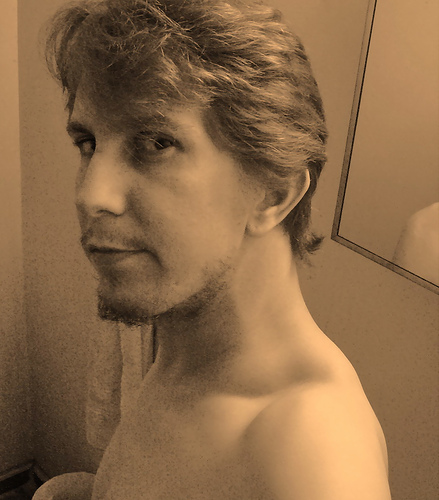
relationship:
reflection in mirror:
[361, 173, 437, 278] [331, 3, 436, 298]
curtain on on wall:
[62, 307, 165, 456] [22, 0, 439, 500]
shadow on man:
[97, 252, 253, 449] [47, 28, 337, 477]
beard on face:
[91, 251, 234, 342] [66, 52, 230, 325]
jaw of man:
[136, 190, 214, 285] [47, 28, 337, 477]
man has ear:
[47, 28, 337, 477] [235, 162, 327, 232]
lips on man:
[77, 232, 161, 277] [47, 28, 337, 477]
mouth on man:
[62, 225, 176, 283] [47, 28, 337, 477]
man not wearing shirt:
[47, 28, 337, 477] [74, 343, 379, 499]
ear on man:
[235, 162, 327, 232] [47, 28, 337, 477]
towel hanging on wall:
[62, 307, 165, 456] [7, 165, 177, 489]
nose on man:
[73, 151, 122, 224] [47, 28, 337, 477]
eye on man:
[128, 112, 186, 172] [47, 28, 337, 477]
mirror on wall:
[331, 3, 436, 298] [245, 10, 431, 374]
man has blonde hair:
[47, 28, 337, 477] [37, 0, 327, 266]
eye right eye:
[68, 128, 98, 163] [45, 114, 113, 169]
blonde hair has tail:
[37, 0, 327, 266] [276, 184, 331, 287]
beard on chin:
[91, 251, 234, 342] [68, 270, 202, 338]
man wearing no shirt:
[47, 28, 337, 477] [74, 343, 379, 499]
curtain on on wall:
[82, 314, 167, 456] [22, 0, 439, 500]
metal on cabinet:
[321, 10, 394, 248] [331, 3, 436, 298]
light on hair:
[185, 39, 327, 110] [68, 270, 202, 338]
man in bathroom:
[47, 28, 337, 477] [0, 10, 429, 499]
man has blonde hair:
[47, 28, 337, 477] [46, 8, 334, 92]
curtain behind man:
[62, 307, 165, 456] [47, 28, 337, 477]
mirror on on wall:
[331, 3, 436, 298] [22, 0, 439, 500]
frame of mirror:
[321, 10, 394, 248] [331, 3, 436, 298]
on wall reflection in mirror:
[22, 0, 439, 500] [331, 3, 436, 298]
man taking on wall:
[47, 28, 337, 477] [22, 0, 439, 500]